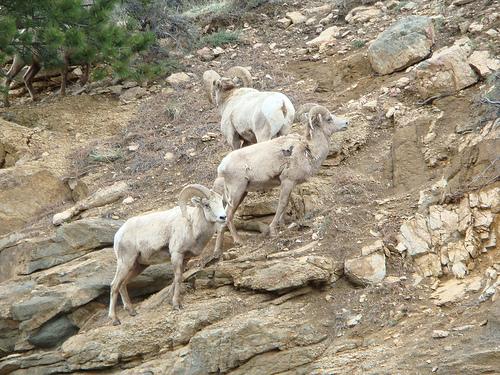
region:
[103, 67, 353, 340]
mountain goats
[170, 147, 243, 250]
they have huge horns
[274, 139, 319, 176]
this goat looks rather beat up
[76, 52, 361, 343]
3 goats are in the photo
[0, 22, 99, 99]
another animal is behind the bushes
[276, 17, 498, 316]
the area is extremely rocky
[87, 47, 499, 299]
the entire area appears desolate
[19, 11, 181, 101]
the evergreen tree hides the other animal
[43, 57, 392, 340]
these goats live in this rocky terrain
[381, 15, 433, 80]
the rock appears to have moss on it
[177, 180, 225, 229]
Large horn on animal's head.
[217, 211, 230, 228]
Animal has black nose.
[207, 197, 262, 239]
Animal has white face.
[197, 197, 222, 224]
Animal has dark eye.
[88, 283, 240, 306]
Animal has white legs.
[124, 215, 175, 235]
Animal has white back.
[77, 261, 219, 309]
Animal is standing on hillside.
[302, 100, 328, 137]
Large horns on animals head.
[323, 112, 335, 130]
Animal has dark eye.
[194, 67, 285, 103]
Large animal has large horns.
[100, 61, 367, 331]
rams on the side of a cliff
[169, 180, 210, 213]
horn that is curved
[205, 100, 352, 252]
ram that is looking up the cliff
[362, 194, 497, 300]
rock formation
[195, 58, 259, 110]
two thick horns coming out of the head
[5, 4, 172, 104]
small tree on the side of the cliff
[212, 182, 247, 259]
leg stretched behind the body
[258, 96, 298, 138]
ram's behind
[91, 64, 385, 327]
group of three rams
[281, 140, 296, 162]
black spot on the fur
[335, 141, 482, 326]
hard rocks are visible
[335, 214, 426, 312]
hard rocks are visible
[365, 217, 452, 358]
hard rocks are visible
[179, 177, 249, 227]
Horns on the ram.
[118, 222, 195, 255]
The ram is white.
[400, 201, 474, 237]
Rock in the dirt.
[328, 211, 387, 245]
The dirt is brown.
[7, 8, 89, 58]
The tree is green.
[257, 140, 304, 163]
Brown on the ram.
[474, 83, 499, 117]
Dark on the dirt.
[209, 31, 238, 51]
Grass in the dirt.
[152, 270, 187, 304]
The leg is pink.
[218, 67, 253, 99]
Brown on the neck.